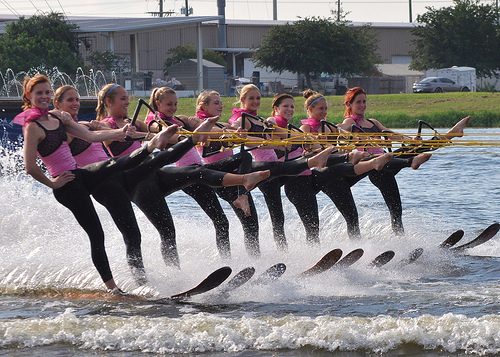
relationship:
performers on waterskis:
[15, 63, 475, 284] [12, 239, 497, 311]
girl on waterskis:
[6, 69, 183, 299] [4, 235, 498, 316]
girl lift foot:
[6, 69, 183, 299] [79, 110, 484, 197]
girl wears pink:
[6, 69, 183, 299] [44, 146, 380, 158]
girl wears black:
[6, 69, 183, 299] [52, 179, 421, 277]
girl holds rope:
[6, 69, 183, 299] [135, 124, 498, 153]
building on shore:
[2, 10, 498, 90] [1, 86, 499, 133]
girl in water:
[6, 69, 183, 299] [19, 195, 491, 355]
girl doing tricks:
[6, 69, 183, 299] [10, 43, 499, 308]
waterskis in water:
[157, 239, 475, 308] [8, 181, 498, 353]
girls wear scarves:
[12, 59, 479, 277] [17, 112, 377, 126]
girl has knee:
[92, 75, 281, 191] [184, 159, 214, 184]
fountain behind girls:
[2, 54, 120, 97] [12, 59, 479, 277]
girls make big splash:
[12, 59, 479, 277] [6, 204, 482, 307]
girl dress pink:
[6, 69, 183, 299] [35, 139, 387, 171]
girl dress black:
[6, 69, 183, 299] [53, 164, 425, 271]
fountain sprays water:
[0, 54, 123, 99] [2, 55, 127, 84]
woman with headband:
[263, 92, 393, 245] [306, 92, 326, 112]